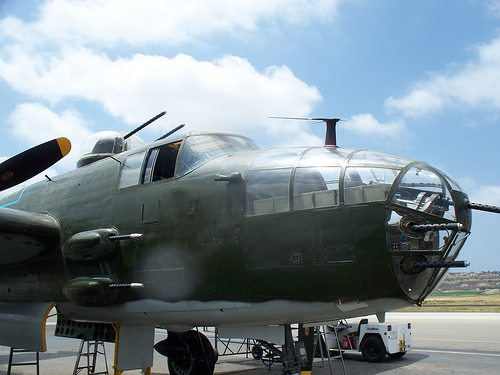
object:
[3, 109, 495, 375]
airplane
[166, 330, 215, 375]
wheel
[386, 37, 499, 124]
clouds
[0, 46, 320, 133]
clouds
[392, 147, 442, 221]
ground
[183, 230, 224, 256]
metal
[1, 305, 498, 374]
ground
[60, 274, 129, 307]
engine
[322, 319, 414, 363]
vehicle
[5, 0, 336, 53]
cloud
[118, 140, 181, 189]
window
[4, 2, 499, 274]
sky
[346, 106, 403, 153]
cloud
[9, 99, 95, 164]
cloud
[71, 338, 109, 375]
ladder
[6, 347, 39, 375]
ladder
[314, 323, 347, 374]
ladder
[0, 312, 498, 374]
tarmac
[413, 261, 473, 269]
metal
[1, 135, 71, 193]
propeller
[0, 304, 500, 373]
airport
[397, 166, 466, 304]
nose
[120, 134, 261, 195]
cockpit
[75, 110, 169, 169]
turret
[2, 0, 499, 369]
scene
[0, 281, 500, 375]
land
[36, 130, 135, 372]
accents